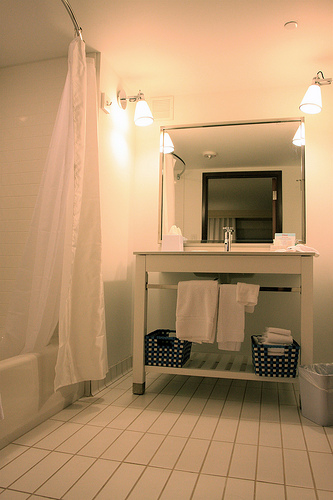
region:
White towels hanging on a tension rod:
[151, 278, 257, 343]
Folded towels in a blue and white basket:
[250, 326, 299, 378]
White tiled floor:
[97, 399, 295, 496]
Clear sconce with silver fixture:
[113, 84, 155, 127]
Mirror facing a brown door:
[157, 124, 306, 244]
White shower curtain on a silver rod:
[39, 23, 110, 384]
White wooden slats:
[194, 350, 248, 374]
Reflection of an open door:
[198, 170, 281, 234]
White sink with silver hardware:
[189, 225, 258, 278]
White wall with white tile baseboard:
[90, 355, 130, 394]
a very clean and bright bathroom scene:
[3, 3, 327, 492]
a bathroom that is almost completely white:
[3, 3, 330, 494]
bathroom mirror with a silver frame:
[156, 116, 305, 245]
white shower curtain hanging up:
[24, 26, 109, 388]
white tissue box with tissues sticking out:
[159, 223, 185, 250]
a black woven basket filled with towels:
[249, 325, 300, 378]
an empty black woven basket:
[144, 326, 190, 368]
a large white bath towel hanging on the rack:
[174, 278, 217, 344]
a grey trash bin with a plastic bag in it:
[298, 359, 332, 424]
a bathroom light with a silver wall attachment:
[112, 85, 153, 129]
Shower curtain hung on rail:
[19, 30, 108, 392]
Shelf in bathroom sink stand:
[143, 350, 299, 386]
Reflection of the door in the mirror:
[199, 170, 282, 241]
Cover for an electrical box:
[283, 19, 297, 33]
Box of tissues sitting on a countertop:
[161, 225, 181, 251]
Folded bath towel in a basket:
[264, 332, 293, 343]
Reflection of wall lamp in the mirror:
[292, 122, 302, 147]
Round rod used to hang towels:
[145, 282, 302, 293]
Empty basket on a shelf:
[144, 326, 190, 367]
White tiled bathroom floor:
[1, 366, 332, 498]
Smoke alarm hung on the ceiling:
[200, 149, 219, 159]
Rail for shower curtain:
[55, 0, 88, 43]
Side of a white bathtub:
[0, 337, 85, 449]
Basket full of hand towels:
[250, 326, 298, 377]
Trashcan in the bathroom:
[298, 362, 331, 425]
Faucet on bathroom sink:
[221, 225, 234, 252]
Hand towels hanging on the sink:
[174, 279, 261, 350]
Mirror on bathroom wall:
[158, 116, 307, 245]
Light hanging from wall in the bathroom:
[298, 69, 332, 115]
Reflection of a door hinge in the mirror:
[271, 189, 280, 201]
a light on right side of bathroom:
[285, 65, 329, 122]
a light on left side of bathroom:
[113, 79, 154, 131]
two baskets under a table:
[147, 315, 298, 387]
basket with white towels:
[248, 317, 306, 380]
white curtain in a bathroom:
[30, 31, 117, 389]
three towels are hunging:
[165, 279, 266, 357]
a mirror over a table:
[152, 111, 309, 244]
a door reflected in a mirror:
[193, 165, 290, 246]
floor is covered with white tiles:
[16, 405, 299, 494]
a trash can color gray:
[293, 359, 331, 430]